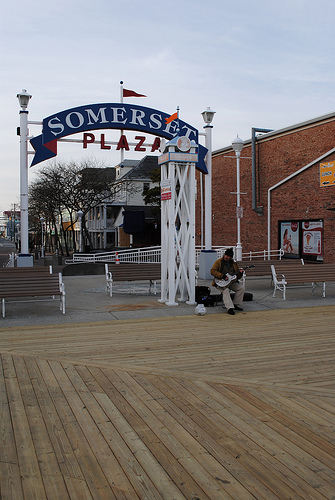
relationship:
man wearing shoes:
[210, 246, 252, 316] [225, 302, 242, 313]